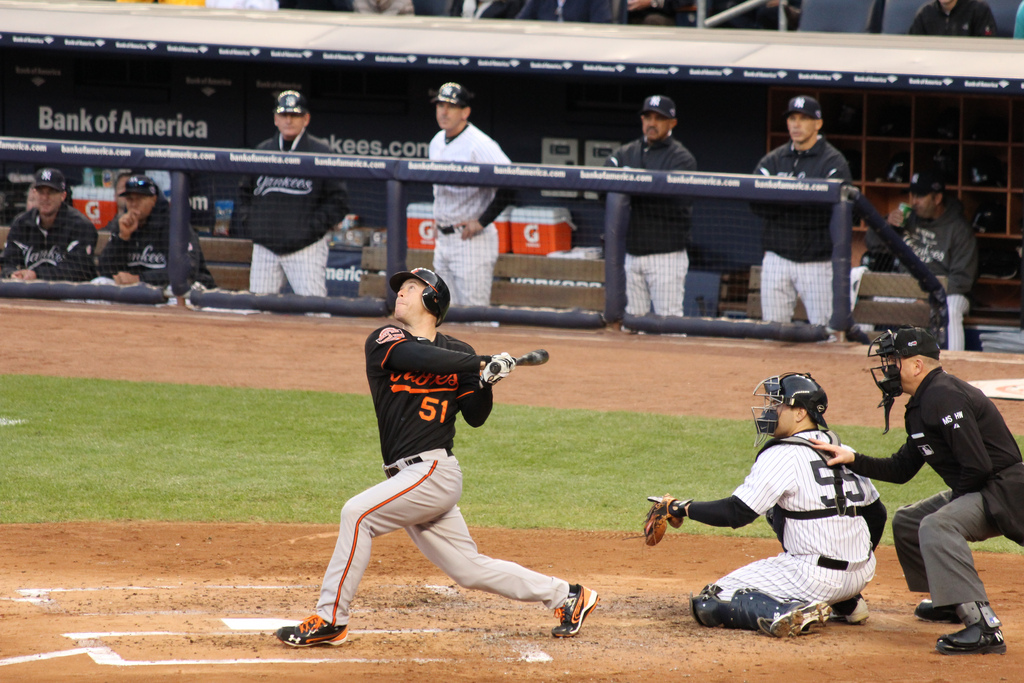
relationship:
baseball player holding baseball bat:
[299, 266, 608, 647] [488, 349, 549, 376]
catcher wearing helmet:
[638, 361, 887, 638] [779, 364, 829, 423]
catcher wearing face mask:
[638, 361, 887, 638] [751, 372, 784, 433]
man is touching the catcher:
[815, 314, 993, 650] [638, 361, 887, 638]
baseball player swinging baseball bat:
[271, 266, 605, 648] [484, 344, 551, 375]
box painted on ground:
[13, 577, 551, 666] [2, 296, 992, 677]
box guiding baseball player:
[13, 577, 551, 666] [271, 266, 605, 648]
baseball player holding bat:
[271, 266, 605, 648] [486, 342, 553, 377]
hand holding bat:
[475, 355, 512, 382] [486, 342, 553, 377]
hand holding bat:
[490, 346, 517, 370] [486, 342, 553, 377]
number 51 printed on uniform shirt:
[415, 392, 454, 423] [361, 320, 496, 463]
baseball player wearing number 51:
[271, 266, 605, 648] [415, 392, 454, 423]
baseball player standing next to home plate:
[271, 266, 605, 648] [220, 612, 309, 634]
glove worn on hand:
[637, 491, 687, 548] [644, 491, 688, 518]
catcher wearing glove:
[638, 361, 887, 638] [637, 491, 687, 548]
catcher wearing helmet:
[638, 361, 887, 638] [760, 368, 830, 429]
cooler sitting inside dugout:
[506, 201, 578, 253] [2, 3, 992, 356]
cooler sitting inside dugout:
[490, 201, 517, 253] [2, 3, 992, 356]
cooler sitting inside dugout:
[402, 197, 441, 250] [2, 3, 992, 356]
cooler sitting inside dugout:
[65, 178, 124, 230] [2, 3, 992, 356]